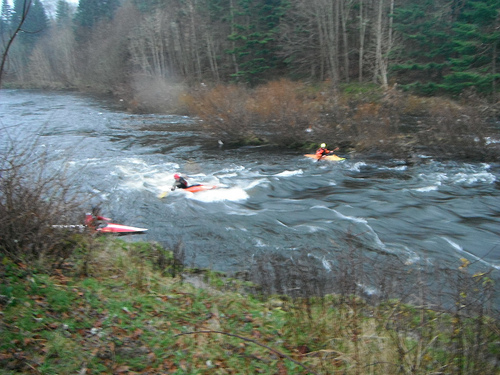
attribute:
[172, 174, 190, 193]
person — sitting, kayaking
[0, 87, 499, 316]
river — here, flowing, rapid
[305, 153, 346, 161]
kayak — yellow, orange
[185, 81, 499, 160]
grass — dry, bare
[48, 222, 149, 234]
kayak — red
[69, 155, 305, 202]
wave — white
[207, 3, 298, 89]
tree — bare, tall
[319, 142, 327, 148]
helmet — white, yellow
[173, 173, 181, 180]
helmet — orange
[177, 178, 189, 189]
jacket — dark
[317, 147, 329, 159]
jacket — orange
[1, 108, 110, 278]
bush — bare, here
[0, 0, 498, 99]
trees — here